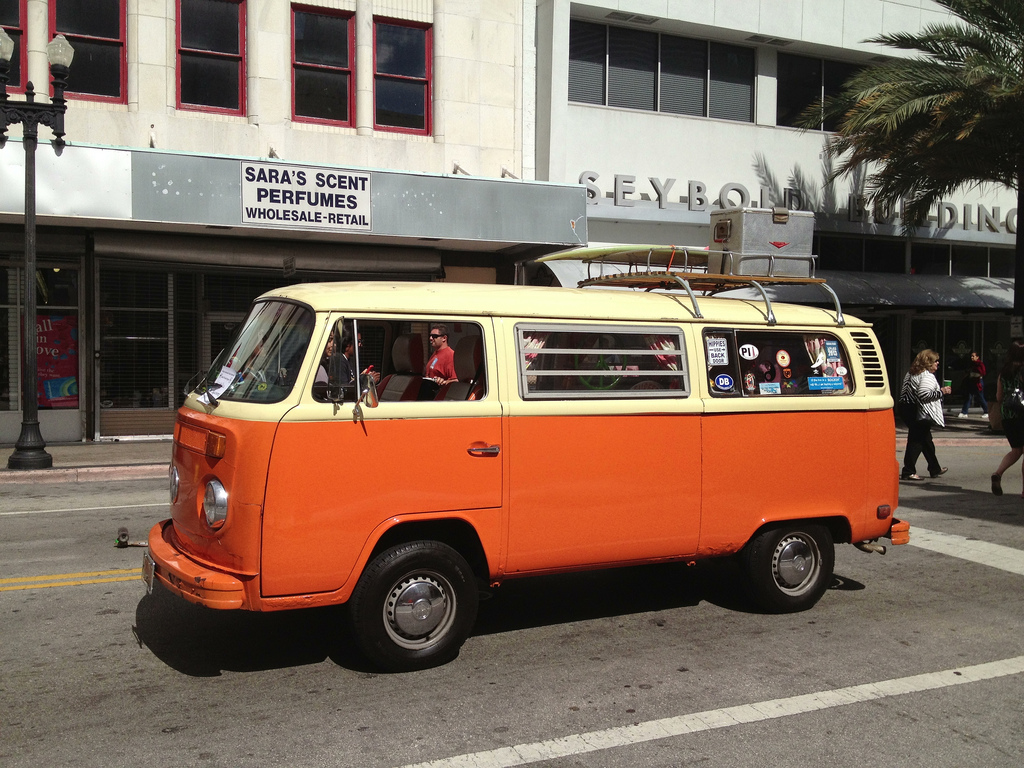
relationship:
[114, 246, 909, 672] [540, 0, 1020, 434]
van in the building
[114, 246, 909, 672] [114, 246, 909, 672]
van above van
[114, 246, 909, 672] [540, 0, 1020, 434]
van next to building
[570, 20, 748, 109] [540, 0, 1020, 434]
window next to building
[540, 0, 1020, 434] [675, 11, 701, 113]
building containing window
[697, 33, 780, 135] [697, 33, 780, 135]
building containing window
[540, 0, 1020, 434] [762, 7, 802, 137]
building with window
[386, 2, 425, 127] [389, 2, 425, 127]
window on building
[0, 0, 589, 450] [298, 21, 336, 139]
building with window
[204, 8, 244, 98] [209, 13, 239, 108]
window in building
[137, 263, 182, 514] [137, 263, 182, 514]
window inside building